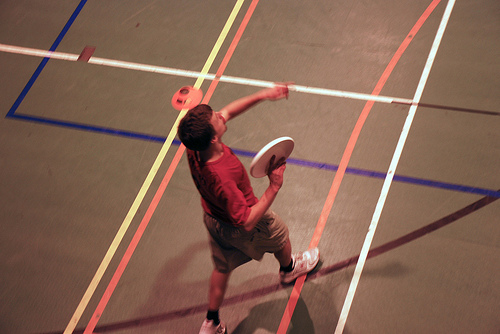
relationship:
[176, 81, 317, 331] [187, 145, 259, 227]
man has red shirt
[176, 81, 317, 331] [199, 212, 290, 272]
man has khaki pants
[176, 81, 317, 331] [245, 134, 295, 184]
man has frisbee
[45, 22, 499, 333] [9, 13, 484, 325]
line on court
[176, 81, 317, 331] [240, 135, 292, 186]
man holding frisbee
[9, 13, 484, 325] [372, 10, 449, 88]
court has lines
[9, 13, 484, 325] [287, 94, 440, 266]
court has lines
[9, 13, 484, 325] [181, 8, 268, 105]
court has lines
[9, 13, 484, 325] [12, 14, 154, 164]
court has lines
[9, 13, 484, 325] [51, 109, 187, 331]
court has lines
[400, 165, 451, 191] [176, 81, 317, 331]
line under man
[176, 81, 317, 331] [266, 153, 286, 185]
man has hand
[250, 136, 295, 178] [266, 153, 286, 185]
frisbee in hand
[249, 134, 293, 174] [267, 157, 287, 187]
frisbee in hand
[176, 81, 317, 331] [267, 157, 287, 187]
man has hand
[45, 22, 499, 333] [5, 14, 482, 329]
line on floor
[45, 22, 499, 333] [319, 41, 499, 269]
line painted on floor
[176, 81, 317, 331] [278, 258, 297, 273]
man has black sock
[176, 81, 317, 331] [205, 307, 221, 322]
man has black sock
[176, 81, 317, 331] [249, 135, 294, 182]
man holding frisbee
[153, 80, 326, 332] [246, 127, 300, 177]
man holding frisbee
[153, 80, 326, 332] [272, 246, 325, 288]
man has shoes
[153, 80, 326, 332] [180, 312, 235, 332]
man has shoes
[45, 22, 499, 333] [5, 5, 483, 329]
line painted on floor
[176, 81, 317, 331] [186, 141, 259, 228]
man wearing red shirt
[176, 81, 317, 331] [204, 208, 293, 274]
man wearing shorts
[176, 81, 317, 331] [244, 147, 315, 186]
man playing frisbee